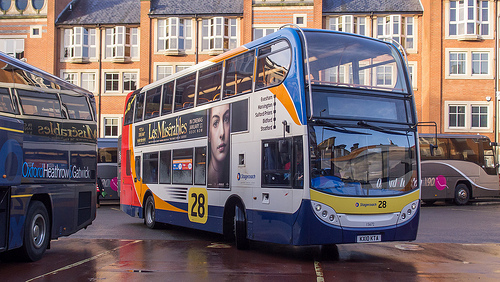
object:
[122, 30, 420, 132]
upper deck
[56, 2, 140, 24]
roof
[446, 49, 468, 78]
window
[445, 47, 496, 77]
windows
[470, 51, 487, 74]
glass window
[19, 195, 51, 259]
tire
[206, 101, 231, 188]
picture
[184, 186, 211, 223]
number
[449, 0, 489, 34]
window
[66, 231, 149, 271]
giraffe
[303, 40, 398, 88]
window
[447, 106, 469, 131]
window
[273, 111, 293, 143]
mirror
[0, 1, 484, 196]
building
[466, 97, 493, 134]
window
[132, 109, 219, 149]
advertisement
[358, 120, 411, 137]
windshield wipers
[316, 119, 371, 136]
windshield wipers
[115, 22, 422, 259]
bus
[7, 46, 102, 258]
bus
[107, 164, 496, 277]
parking lot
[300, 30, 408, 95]
windshield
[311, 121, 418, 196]
windshield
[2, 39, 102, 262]
parked bus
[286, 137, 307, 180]
mirror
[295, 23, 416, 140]
mirror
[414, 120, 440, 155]
mirror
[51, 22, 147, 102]
windows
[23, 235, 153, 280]
line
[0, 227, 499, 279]
pavement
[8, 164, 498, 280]
street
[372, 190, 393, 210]
number